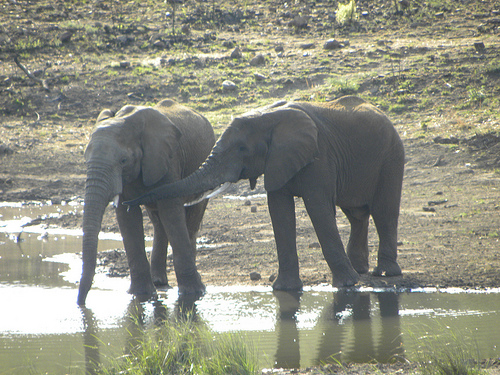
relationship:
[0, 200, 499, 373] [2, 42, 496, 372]
water in watering hole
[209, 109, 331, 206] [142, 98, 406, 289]
head of an elephant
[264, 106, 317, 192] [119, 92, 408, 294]
ear belonging to elephant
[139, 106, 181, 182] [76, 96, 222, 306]
ear belonging to elephant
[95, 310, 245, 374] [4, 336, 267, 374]
grass growing by water hole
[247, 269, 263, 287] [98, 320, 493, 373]
rock in grass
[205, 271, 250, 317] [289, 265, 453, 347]
light on surface of water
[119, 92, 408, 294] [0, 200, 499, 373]
elephant standing near water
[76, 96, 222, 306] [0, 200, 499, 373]
elephant standing near water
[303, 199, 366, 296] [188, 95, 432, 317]
leg of elephant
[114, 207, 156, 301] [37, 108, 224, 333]
leg of elephant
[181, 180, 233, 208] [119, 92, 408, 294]
tusk on elephant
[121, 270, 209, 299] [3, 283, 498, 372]
elephant's feet in water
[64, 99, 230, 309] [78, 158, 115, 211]
elephant has wrinkles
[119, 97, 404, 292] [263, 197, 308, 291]
elephant has leg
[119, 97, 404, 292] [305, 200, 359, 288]
elephant has leg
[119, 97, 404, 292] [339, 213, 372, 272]
elephant has leg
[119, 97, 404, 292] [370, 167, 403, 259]
elephant has elephant leg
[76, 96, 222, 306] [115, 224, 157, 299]
elephant has leg